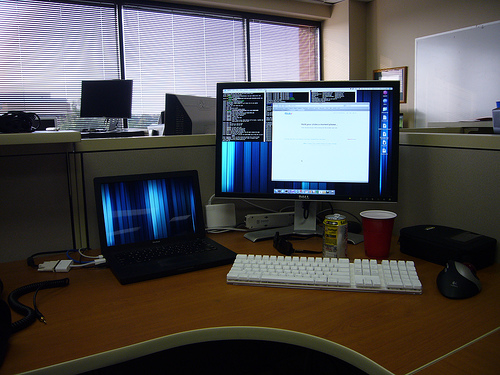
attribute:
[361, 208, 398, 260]
cup — plastic, red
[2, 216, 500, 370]
desk — brow, wood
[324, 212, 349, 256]
can — open, silver, yellow, soda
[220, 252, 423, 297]
keyboard — bulky, white, computer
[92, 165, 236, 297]
laptop — open, black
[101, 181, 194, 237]
lines — blue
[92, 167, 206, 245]
screen — light blue, laptop, computer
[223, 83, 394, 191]
screen — illuminated, computer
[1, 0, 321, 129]
blinds — open, white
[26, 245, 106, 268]
cables — plugged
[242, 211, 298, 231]
strip — power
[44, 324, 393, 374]
edge — roud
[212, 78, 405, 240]
desktop — black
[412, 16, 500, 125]
board — dry erase, white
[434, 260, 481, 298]
mouse — black, silver, computer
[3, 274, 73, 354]
cords — black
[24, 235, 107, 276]
wires — plugged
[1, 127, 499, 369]
cubicle — office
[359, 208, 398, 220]
trim — white